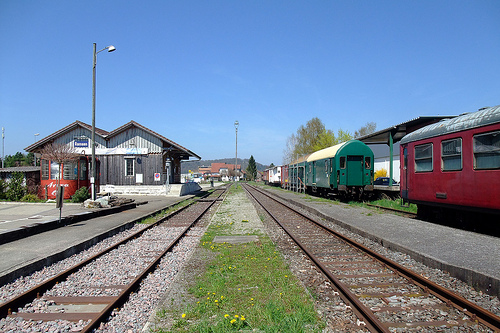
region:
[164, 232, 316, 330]
the grass between the tracks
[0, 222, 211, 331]
the rocks on the railroad tracks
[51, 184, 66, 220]
the sign in the parking lot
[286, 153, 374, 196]
the green train car on the tracks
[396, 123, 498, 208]
the red train car on the tracks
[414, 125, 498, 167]
the row of windows on the train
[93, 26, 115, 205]
the light in the parking lot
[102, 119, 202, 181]
the building on the platform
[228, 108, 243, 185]
the light between the train tracks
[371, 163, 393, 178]
the yellow trees over the car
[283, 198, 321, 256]
Railroad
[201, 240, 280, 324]
Green color plants with yellow color flower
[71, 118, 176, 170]
Building near the platform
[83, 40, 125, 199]
Metal pole with lights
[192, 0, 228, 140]
A blue color sky with clouds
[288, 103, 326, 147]
Tree with green leaves and branches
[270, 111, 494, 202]
Train parked in the railway station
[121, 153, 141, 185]
Window of the building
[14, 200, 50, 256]
Platform near the railroad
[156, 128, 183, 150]
Roof of the building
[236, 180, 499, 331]
brown train tracks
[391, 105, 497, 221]
red train on train tracks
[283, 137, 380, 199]
green train car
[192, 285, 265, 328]
yellow flowers on green grass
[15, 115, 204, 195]
double roof building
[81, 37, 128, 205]
street lamp on sidewalk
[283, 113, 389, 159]
top of green trees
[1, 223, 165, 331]
grey gravel surrounding train tracks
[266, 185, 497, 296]
grey sidewalk next to train tracks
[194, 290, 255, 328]
the dandelions beside the tracks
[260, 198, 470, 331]
the empty tracks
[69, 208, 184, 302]
the gravel on the tracks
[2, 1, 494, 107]
the sky is blue and clear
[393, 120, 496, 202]
the red train car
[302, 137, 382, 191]
the green train car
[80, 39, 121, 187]
the light on the pole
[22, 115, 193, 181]
the gray building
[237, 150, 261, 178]
the pine tree in the distance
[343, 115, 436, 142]
the awning beside the train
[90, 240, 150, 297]
pebbles on train tracks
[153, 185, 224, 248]
set of train tracks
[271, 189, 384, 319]
set of train tracks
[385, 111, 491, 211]
red train on tracks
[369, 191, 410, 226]
grass on train track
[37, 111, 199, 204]
small building near train tracks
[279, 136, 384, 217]
green train on tracks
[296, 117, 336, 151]
tall green leafy tree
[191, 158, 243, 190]
buildings in the distance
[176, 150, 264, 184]
mountain range in the distance